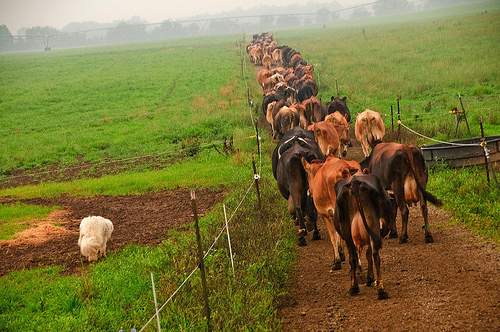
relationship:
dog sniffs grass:
[70, 211, 117, 267] [84, 257, 116, 283]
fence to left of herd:
[109, 32, 261, 332] [245, 33, 443, 300]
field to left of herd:
[1, 33, 268, 332] [245, 33, 443, 300]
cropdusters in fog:
[2, 1, 389, 64] [0, 0, 499, 54]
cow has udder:
[327, 167, 397, 306] [348, 204, 373, 258]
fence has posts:
[271, 33, 499, 215] [271, 33, 499, 189]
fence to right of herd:
[271, 33, 499, 215] [245, 33, 443, 300]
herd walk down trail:
[245, 33, 443, 300] [244, 31, 499, 330]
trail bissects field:
[244, 31, 499, 330] [2, 9, 499, 331]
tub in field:
[420, 130, 499, 177] [2, 9, 499, 331]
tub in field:
[420, 136, 500, 173] [2, 9, 499, 331]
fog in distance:
[0, 0, 499, 54] [2, 1, 497, 57]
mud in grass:
[1, 142, 240, 290] [1, 13, 499, 330]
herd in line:
[245, 33, 443, 300] [244, 34, 468, 331]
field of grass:
[2, 9, 499, 331] [1, 13, 499, 330]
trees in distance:
[1, 0, 499, 56] [2, 1, 497, 57]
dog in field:
[70, 211, 117, 267] [2, 9, 499, 331]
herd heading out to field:
[242, 25, 450, 304] [0, 0, 500, 332]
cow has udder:
[357, 139, 446, 249] [395, 168, 424, 210]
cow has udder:
[267, 122, 325, 250] [283, 192, 307, 228]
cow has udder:
[353, 106, 389, 167] [365, 131, 378, 146]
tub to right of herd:
[420, 136, 500, 173] [245, 33, 443, 300]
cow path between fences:
[248, 25, 499, 331] [137, 30, 500, 331]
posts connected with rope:
[271, 33, 499, 189] [399, 120, 488, 160]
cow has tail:
[327, 167, 397, 306] [349, 186, 384, 252]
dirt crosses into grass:
[215, 134, 302, 332] [1, 13, 499, 330]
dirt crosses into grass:
[346, 125, 424, 168] [1, 13, 499, 330]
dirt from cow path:
[215, 134, 302, 332] [248, 25, 499, 331]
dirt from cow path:
[346, 125, 424, 168] [248, 25, 499, 331]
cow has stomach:
[296, 150, 367, 273] [308, 181, 337, 221]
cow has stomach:
[327, 167, 397, 306] [378, 179, 399, 241]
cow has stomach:
[267, 122, 325, 250] [275, 157, 288, 197]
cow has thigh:
[327, 167, 397, 306] [329, 208, 353, 249]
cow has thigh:
[327, 167, 397, 306] [365, 212, 384, 245]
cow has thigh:
[357, 139, 446, 249] [415, 159, 431, 197]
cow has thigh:
[357, 139, 446, 249] [384, 162, 407, 201]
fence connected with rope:
[271, 33, 499, 215] [317, 76, 398, 121]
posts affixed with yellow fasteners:
[397, 107, 488, 149] [397, 109, 488, 147]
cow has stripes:
[267, 122, 325, 250] [273, 135, 309, 161]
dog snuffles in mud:
[70, 211, 117, 267] [1, 142, 240, 290]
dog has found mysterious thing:
[70, 211, 117, 267] [88, 263, 94, 268]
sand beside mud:
[1, 204, 82, 258] [1, 142, 240, 290]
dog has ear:
[70, 211, 117, 267] [87, 237, 102, 252]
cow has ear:
[296, 150, 367, 273] [298, 157, 314, 173]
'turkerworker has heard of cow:
[400, 266, 408, 275] [267, 122, 325, 250]